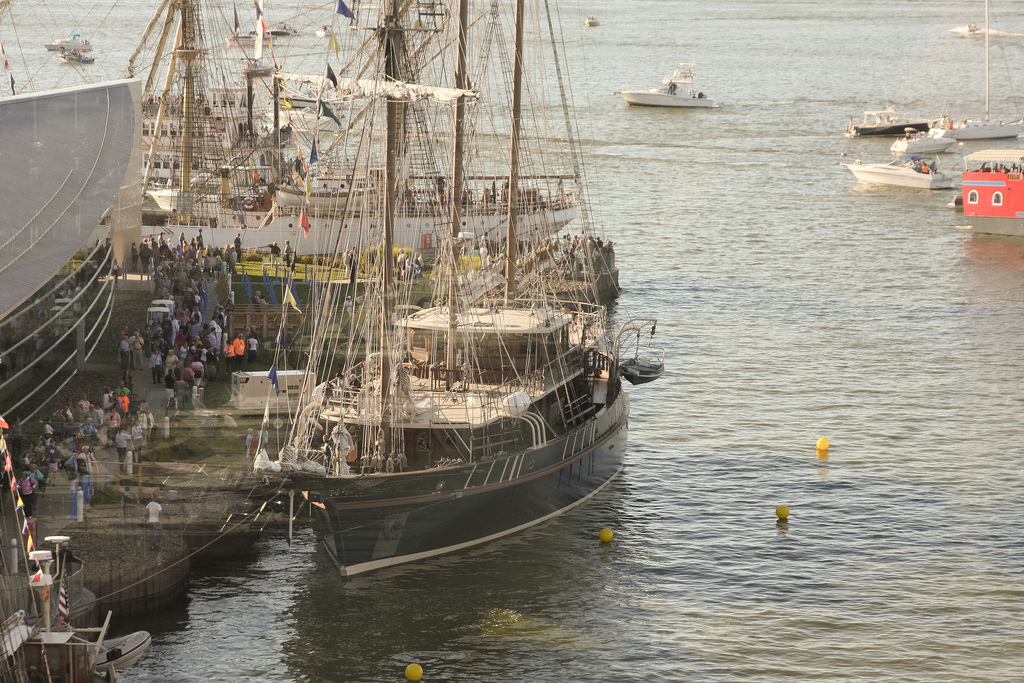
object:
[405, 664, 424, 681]
yellow ball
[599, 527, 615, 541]
yellow ball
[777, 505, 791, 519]
yellow ball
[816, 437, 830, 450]
yellow ball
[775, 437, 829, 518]
yellowballs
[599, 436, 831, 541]
yellowballs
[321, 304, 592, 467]
wall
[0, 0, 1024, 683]
harbor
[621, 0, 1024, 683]
wate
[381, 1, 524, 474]
masts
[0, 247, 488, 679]
dock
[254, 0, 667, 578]
boat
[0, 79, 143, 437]
building